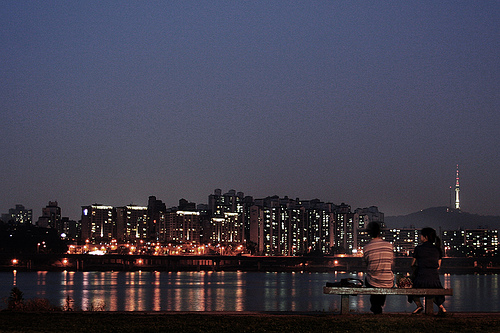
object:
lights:
[11, 269, 18, 287]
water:
[0, 270, 500, 312]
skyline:
[0, 186, 500, 226]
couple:
[363, 221, 449, 315]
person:
[410, 226, 448, 314]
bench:
[321, 286, 455, 314]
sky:
[0, 0, 500, 224]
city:
[0, 188, 500, 270]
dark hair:
[366, 222, 382, 237]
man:
[360, 221, 395, 314]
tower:
[451, 163, 461, 208]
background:
[0, 0, 500, 333]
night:
[0, 0, 500, 333]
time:
[0, 0, 500, 333]